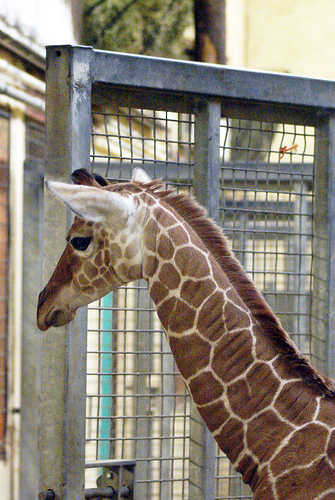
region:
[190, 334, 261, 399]
pattern on side of giraffe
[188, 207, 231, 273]
hair on back of giraffe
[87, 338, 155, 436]
silver metal fencing on gate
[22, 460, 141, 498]
large metal lock on gate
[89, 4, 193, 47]
trees with green leaves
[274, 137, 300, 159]
small orange string tied in knot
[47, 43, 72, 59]
hole in side of metal fencing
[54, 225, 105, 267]
black eye on giraffe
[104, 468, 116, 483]
large silver bolt on gate lock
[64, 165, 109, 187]
black and orange horns on giraffe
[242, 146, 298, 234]
Metal grills in the photo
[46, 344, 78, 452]
A metal bar in the photo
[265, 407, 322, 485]
Brown and white patches on the giraffe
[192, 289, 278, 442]
Long giraffe neck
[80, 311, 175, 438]
A fence in the photo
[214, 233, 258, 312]
Fur in the photo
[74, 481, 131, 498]
A lock in the photo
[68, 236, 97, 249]
Eye of the giraffe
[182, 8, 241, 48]
A pole in the photo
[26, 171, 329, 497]
A giraffe in the photo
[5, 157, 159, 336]
head of giraffe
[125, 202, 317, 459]
long neck of giraffe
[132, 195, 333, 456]
white lines on the giraffe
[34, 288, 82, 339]
closed mouth of giraffe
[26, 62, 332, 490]
a large metal door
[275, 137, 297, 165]
orange string on wire of door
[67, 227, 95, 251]
black eye of giraffe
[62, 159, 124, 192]
two knobs on head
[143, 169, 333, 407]
short mane on neck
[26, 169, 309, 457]
a brown and white giraffe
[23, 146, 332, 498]
a tall giraffe neck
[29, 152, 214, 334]
head of a giraffe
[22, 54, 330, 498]
giraffe held captive in a cage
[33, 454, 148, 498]
locks of the cage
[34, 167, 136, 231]
ear of a giraffe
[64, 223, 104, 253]
eyes of a giraffe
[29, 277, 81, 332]
mouth of a giraffe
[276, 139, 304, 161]
a red zip tie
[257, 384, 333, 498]
pattern on a giraffe skin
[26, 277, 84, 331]
the nose and jaw of giraffe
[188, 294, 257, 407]
wrinkles on a giraffes neck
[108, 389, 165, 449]
metal wiring on a cage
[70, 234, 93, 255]
black eye of a giraffe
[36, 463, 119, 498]
metal bolt on a cage door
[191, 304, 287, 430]
brown spots on a giraffe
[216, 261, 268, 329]
short brown mane on a giraffe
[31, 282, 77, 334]
closed mouth of a giraffe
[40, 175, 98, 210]
ear on a giraffe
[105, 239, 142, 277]
cheek on a giraffe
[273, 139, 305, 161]
orange tie tied to wires